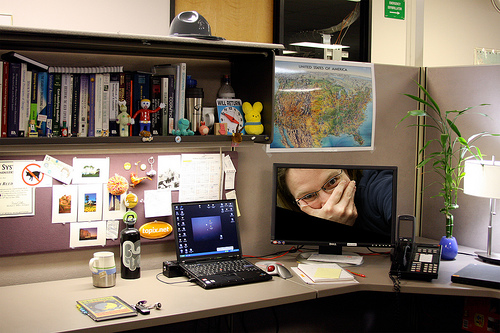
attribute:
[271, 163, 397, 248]
monitor — flat screen, black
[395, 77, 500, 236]
plant — green, small, tall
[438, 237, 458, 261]
vase — purple, blue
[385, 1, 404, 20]
sign — green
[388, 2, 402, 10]
lettering — white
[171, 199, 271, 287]
laptop — open, little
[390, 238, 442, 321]
phone — black, landline phone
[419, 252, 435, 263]
note — white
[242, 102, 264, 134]
bunny — yellow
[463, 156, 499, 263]
lamp — small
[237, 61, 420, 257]
wall — grey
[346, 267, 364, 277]
pen — red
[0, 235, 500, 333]
surface — grey